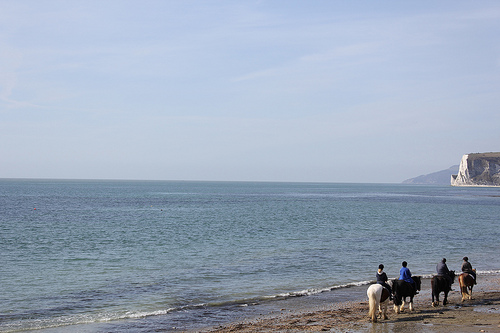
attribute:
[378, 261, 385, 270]
hat — black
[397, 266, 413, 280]
shirt — blue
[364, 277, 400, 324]
horse — white, white+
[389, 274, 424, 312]
horse — brown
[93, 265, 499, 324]
wave — small, white, calm, rolling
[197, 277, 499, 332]
sand — wet, brown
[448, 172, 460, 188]
cliff — tall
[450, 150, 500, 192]
mountain — giant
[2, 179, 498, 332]
ocean — blue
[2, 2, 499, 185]
sky — blue, clear